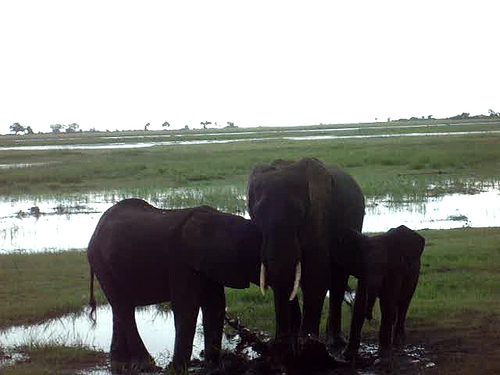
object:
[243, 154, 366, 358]
elephant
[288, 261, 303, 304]
tusk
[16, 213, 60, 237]
water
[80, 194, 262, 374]
elephant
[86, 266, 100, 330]
tail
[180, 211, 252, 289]
ear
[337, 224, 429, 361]
elephant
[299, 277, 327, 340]
leg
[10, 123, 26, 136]
tree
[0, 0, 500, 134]
sky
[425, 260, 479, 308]
grass